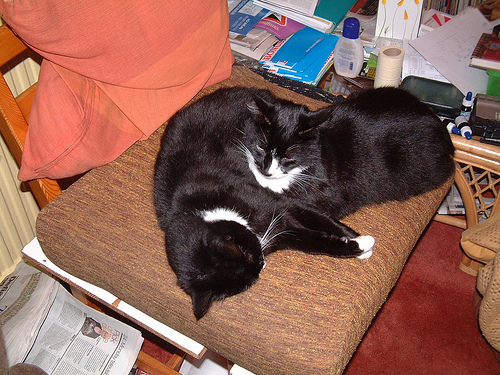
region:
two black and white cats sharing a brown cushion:
[31, 55, 461, 372]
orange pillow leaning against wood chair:
[0, 0, 235, 210]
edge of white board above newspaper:
[0, 235, 205, 365]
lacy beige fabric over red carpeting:
[342, 212, 493, 369]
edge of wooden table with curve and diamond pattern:
[436, 135, 493, 235]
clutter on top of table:
[225, 1, 495, 166]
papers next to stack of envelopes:
[227, 0, 363, 95]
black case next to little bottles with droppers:
[401, 70, 475, 143]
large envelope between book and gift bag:
[370, 0, 497, 96]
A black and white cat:
[235, 87, 457, 219]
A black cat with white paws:
[152, 85, 374, 323]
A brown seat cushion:
[37, 64, 457, 374]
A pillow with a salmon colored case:
[2, 1, 235, 182]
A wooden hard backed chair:
[1, 19, 253, 374]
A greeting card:
[374, 1, 424, 40]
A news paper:
[22, 283, 145, 373]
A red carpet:
[55, 180, 499, 373]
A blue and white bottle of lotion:
[332, 17, 364, 79]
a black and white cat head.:
[228, 88, 340, 195]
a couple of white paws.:
[352, 227, 379, 261]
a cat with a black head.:
[166, 213, 267, 328]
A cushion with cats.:
[34, 70, 458, 373]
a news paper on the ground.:
[0, 267, 145, 372]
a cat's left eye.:
[280, 152, 293, 166]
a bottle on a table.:
[329, 12, 365, 88]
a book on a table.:
[223, 0, 334, 95]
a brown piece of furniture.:
[439, 124, 497, 233]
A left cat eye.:
[281, 148, 298, 169]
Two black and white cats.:
[157, 76, 454, 318]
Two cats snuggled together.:
[154, 84, 455, 324]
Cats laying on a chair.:
[1, 3, 456, 373]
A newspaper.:
[1, 264, 145, 374]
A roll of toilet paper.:
[373, 46, 406, 89]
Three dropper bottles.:
[440, 87, 475, 139]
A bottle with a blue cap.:
[330, 15, 365, 81]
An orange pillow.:
[1, 2, 238, 182]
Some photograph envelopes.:
[255, 22, 340, 88]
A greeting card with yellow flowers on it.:
[371, 0, 423, 39]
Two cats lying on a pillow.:
[33, 63, 453, 373]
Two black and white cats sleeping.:
[150, 83, 455, 323]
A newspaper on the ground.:
[0, 262, 143, 374]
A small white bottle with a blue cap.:
[332, 15, 362, 77]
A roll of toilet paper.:
[375, 43, 405, 85]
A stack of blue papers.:
[256, 28, 337, 84]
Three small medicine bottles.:
[440, 90, 473, 139]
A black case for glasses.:
[397, 75, 464, 117]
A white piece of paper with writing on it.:
[407, 7, 492, 94]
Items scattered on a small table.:
[229, 0, 499, 148]